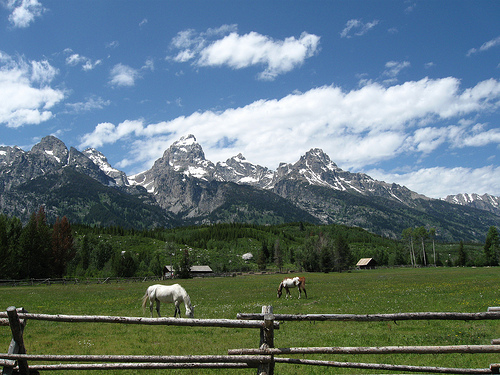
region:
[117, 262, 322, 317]
horses standing in field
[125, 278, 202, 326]
white horse in fiedl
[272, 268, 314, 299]
white and brown horse in field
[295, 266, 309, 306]
brown back legs of horse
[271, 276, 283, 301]
brown neck and head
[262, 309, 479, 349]
wooden fence posts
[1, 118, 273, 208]
large mountain range with snow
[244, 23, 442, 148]
large white clouds in the sky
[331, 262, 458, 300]
green grass in the field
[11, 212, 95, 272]
large green trees in field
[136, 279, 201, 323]
a white horse in a grassy field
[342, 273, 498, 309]
a grassy field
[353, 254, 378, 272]
a small cabin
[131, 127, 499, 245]
large mountain range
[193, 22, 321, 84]
a large cumulus cloud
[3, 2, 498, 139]
a large cloudy sky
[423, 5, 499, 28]
vast blue sky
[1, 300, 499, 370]
a wooden pole fence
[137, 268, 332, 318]
two horses in a field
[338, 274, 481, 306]
a green grassy field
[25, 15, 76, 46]
white clouds in blue sky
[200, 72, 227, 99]
white clouds in blue sky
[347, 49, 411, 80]
white clouds in blue sky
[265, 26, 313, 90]
white clouds in blue sky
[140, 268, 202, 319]
white horse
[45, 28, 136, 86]
white clouds in blue sky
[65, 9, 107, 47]
white clouds in blue sky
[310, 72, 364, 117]
white clouds in blue sky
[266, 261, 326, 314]
a white and brown horse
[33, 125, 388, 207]
snow on the mountains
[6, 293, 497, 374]
a wooden fence line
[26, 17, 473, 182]
white clouds in the sky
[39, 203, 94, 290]
a red tree among green trees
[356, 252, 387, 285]
a small house by trees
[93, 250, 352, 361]
two horses eating grass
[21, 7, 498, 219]
a blue sky with clouds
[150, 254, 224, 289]
a larger house to the left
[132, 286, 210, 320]
white horse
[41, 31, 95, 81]
white clouds in blue sky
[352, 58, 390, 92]
white clouds in blue sky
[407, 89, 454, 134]
white clouds in blue sky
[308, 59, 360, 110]
white clouds in blue sky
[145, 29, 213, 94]
white clouds in blue sky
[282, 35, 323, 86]
white clouds in blue sky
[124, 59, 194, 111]
white clouds in blue sky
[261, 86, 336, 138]
white clouds in blue sky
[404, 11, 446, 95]
white clouds in blue sky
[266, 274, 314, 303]
Horse in the grass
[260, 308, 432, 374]
Fence made of wood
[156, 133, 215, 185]
Snow on a mountain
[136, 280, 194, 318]
Horse eating grass in a field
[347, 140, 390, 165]
Clouds in the sky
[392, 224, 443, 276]
A group of tall trees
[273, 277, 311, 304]
Brown and white horse